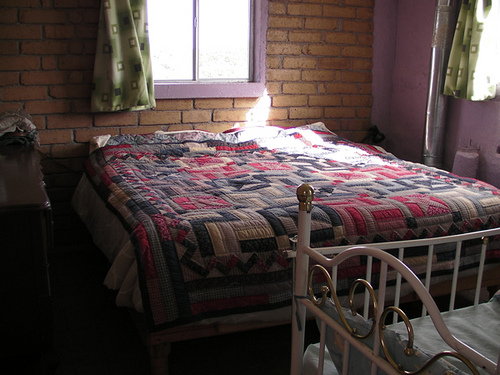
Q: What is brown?
A: Bricks.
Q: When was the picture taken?
A: Daytime.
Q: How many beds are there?
A: Two.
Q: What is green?
A: Curtains.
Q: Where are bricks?
A: On the wall.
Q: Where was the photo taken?
A: In a bedroom.